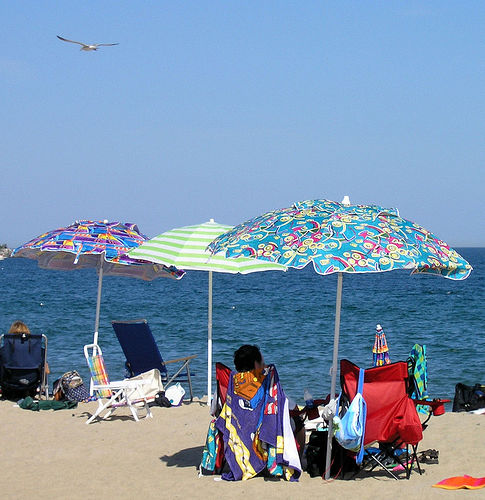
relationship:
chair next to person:
[336, 355, 423, 460] [228, 340, 262, 371]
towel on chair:
[218, 363, 302, 483] [211, 362, 313, 486]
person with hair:
[214, 339, 306, 468] [234, 344, 261, 372]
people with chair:
[210, 344, 299, 432] [183, 330, 407, 497]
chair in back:
[86, 342, 148, 428] [87, 354, 108, 390]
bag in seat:
[314, 359, 372, 458] [328, 320, 424, 467]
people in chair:
[210, 344, 299, 432] [210, 357, 300, 478]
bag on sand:
[452, 381, 484, 410] [0, 403, 482, 496]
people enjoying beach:
[232, 344, 265, 386] [4, 403, 481, 497]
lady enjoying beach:
[9, 321, 50, 376] [4, 403, 481, 497]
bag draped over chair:
[333, 366, 368, 466] [99, 302, 208, 408]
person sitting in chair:
[234, 337, 287, 377] [213, 361, 275, 470]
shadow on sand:
[159, 441, 201, 477] [0, 403, 482, 496]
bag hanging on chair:
[332, 368, 366, 465] [312, 356, 451, 480]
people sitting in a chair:
[210, 344, 299, 432] [218, 360, 277, 482]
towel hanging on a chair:
[200, 364, 300, 480] [218, 360, 277, 482]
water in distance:
[38, 243, 481, 421] [2, 148, 484, 294]